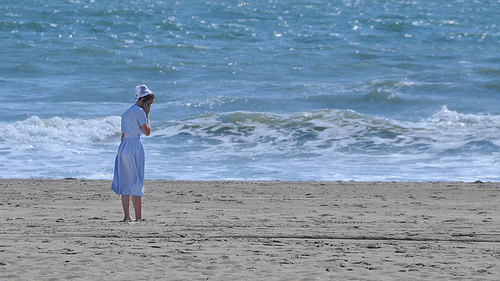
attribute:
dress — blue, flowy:
[112, 105, 148, 198]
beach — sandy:
[0, 177, 499, 280]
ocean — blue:
[1, 0, 498, 182]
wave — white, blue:
[0, 108, 499, 153]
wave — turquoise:
[347, 75, 424, 104]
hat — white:
[135, 84, 154, 101]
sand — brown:
[56, 218, 63, 223]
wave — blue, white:
[15, 20, 58, 35]